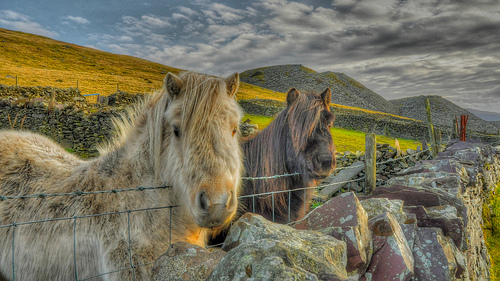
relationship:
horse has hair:
[236, 84, 338, 217] [243, 93, 321, 214]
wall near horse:
[150, 137, 493, 279] [236, 84, 338, 217]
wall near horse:
[150, 137, 493, 279] [1, 68, 245, 280]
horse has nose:
[236, 84, 338, 217] [312, 152, 334, 170]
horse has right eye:
[1, 68, 245, 280] [171, 123, 182, 139]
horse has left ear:
[236, 84, 338, 217] [318, 85, 334, 105]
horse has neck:
[236, 84, 338, 217] [244, 112, 307, 215]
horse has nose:
[1, 68, 245, 280] [197, 188, 234, 216]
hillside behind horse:
[1, 30, 499, 196] [236, 84, 338, 217]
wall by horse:
[150, 137, 493, 279] [236, 84, 338, 217]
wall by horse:
[150, 137, 493, 279] [1, 68, 245, 280]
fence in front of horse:
[5, 111, 483, 280] [236, 84, 338, 217]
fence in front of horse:
[5, 111, 483, 280] [1, 68, 245, 280]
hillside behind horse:
[1, 30, 499, 196] [1, 68, 245, 280]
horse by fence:
[236, 84, 338, 217] [5, 111, 483, 280]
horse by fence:
[1, 68, 245, 280] [5, 111, 483, 280]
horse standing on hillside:
[236, 84, 338, 217] [1, 30, 499, 196]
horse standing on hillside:
[1, 68, 245, 280] [1, 30, 499, 196]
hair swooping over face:
[243, 93, 321, 214] [295, 101, 335, 172]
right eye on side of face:
[171, 123, 182, 139] [168, 94, 243, 227]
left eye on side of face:
[229, 125, 240, 139] [168, 94, 243, 227]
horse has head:
[1, 68, 245, 280] [155, 73, 245, 223]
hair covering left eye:
[171, 70, 222, 145] [229, 125, 240, 139]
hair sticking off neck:
[98, 92, 169, 156] [92, 118, 212, 248]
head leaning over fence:
[155, 73, 245, 223] [5, 111, 483, 280]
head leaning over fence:
[285, 96, 334, 182] [5, 111, 483, 280]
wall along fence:
[150, 137, 493, 279] [5, 111, 483, 280]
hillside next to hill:
[1, 30, 499, 196] [231, 63, 360, 113]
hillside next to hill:
[1, 30, 499, 196] [384, 83, 489, 132]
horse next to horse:
[236, 84, 338, 217] [1, 68, 245, 280]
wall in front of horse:
[150, 137, 493, 279] [236, 84, 338, 217]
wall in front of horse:
[150, 137, 493, 279] [1, 68, 245, 280]